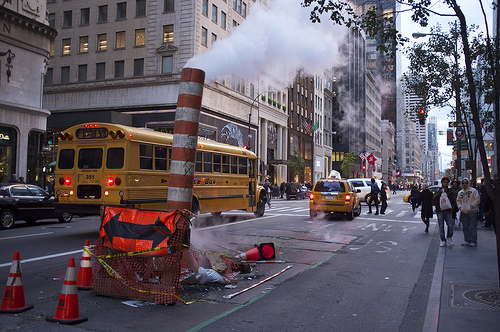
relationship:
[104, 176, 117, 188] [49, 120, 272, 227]
brake light on a bus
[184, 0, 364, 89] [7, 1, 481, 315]
smoke rising in a city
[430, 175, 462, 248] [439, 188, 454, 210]
man with a bag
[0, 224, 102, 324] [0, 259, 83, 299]
cones with stripes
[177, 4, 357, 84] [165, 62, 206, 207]
steam emitting from cylinder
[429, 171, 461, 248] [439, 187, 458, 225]
man carrying bag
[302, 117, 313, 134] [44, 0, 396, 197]
flag flying from building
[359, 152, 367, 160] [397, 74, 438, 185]
flag flying from building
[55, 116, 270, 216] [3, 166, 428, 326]
bus on road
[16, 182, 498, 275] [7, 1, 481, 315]
people in city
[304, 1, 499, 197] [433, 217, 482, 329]
tree on sidewalk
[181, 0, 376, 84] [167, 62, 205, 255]
smoke coming from object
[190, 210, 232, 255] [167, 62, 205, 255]
smoke coming from object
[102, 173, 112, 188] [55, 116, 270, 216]
light on back of bus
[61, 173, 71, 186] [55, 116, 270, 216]
light on back of bus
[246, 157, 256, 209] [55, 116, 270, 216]
doors to bus